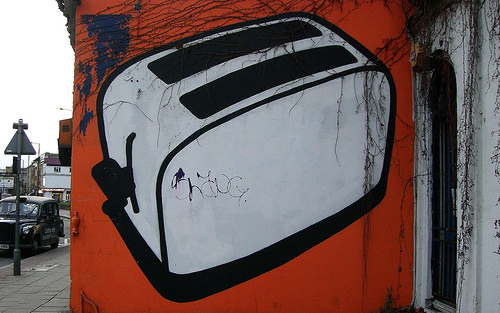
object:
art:
[89, 11, 395, 304]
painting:
[102, 16, 386, 298]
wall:
[103, 10, 401, 310]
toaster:
[95, 13, 390, 303]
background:
[74, 16, 416, 310]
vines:
[354, 30, 405, 199]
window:
[408, 51, 465, 309]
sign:
[2, 119, 41, 155]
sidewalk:
[7, 255, 71, 313]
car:
[0, 195, 65, 257]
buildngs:
[28, 152, 70, 194]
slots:
[145, 12, 355, 120]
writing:
[170, 166, 250, 206]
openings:
[143, 19, 323, 87]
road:
[0, 176, 69, 312]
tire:
[24, 239, 38, 256]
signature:
[168, 166, 256, 207]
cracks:
[36, 289, 60, 309]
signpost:
[13, 153, 24, 276]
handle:
[90, 158, 128, 199]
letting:
[41, 225, 59, 244]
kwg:
[170, 166, 250, 207]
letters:
[169, 166, 193, 202]